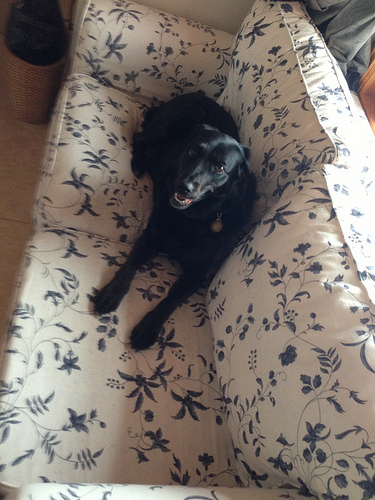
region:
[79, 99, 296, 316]
dog on the couch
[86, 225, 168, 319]
leg of the dog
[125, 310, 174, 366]
paw of the dog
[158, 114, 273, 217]
head of the dog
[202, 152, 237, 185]
eye of the dog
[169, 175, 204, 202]
nose of the dog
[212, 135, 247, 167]
light hitting the dog's head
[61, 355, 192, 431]
blue and white couch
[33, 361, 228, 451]
design on the couch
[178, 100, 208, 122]
black fur on the dog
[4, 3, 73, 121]
black bag in basket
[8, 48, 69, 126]
side of tan wicker basket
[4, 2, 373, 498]
white couch with flower print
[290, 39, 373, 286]
light reflection on top of cushion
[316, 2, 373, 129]
curtain on side of window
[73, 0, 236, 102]
arm rest on end of couch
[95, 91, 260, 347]
dog reclined on couch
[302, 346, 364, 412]
black leaves on white material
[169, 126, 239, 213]
brown eyes on dog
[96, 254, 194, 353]
black paws of dog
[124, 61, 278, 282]
black dog on sofa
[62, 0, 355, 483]
sofa is blue and white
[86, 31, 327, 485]
blue flowers on sofa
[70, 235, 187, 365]
dog has black paws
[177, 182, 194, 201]
dog has black nose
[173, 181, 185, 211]
dog's mouth is open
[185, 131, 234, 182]
dog's eyes are brown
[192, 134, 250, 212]
dog has long black ears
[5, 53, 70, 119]
wicker basket next to sofa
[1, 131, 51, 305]
floor beneath sofa is brown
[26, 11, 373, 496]
there is a dog on the sofa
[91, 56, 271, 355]
the dog on the sofa is black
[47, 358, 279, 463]
the sofa has a flower pattern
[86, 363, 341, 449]
the sofa is white with a grey flower pattern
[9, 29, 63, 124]
there is a wicker basket next to the sofa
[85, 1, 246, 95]
this is the arm to the sofa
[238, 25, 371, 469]
this area is the back of the sofa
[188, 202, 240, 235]
the dog is wearing a collar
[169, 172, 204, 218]
the dogs mouth is open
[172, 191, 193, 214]
the dogs teeth are visible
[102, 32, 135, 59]
flower on the couch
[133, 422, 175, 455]
flower on the couch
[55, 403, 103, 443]
flower on the couch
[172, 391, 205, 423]
flower on the couch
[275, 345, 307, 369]
flower on the couch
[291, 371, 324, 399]
flower on the couch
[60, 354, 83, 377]
flower on the couch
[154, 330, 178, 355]
flower on the couch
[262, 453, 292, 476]
flower on the couch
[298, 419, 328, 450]
flower on the couch